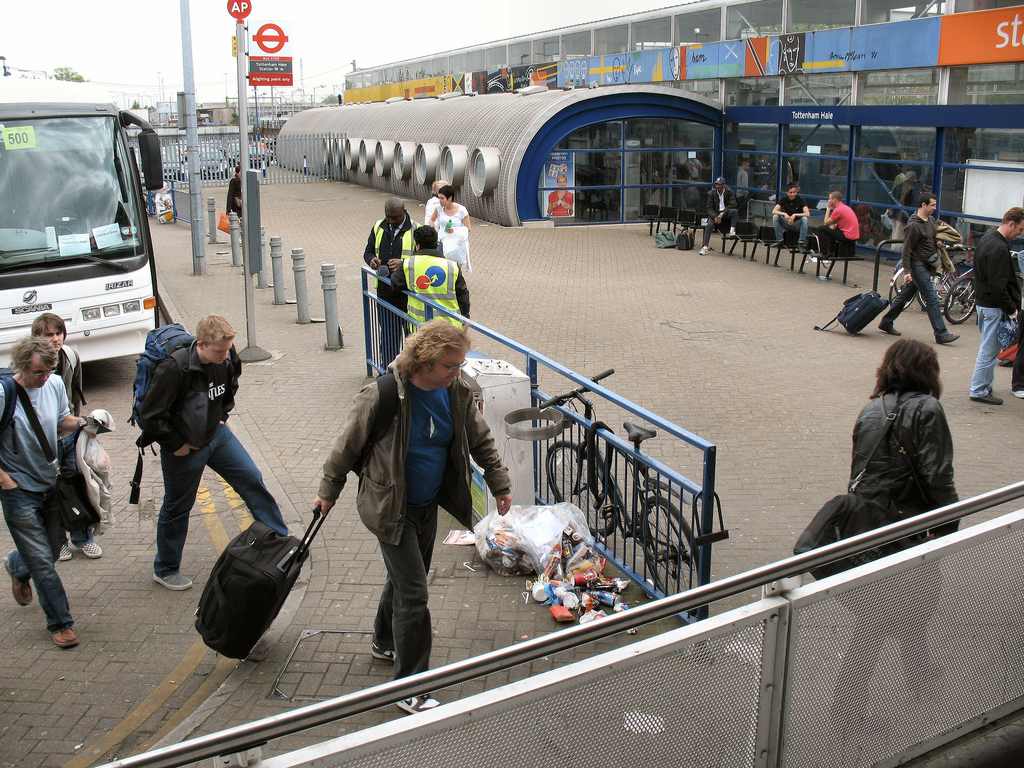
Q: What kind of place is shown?
A: It is a road.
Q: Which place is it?
A: It is a road.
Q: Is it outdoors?
A: Yes, it is outdoors.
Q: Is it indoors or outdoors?
A: It is outdoors.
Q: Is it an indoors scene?
A: No, it is outdoors.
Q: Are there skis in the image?
A: No, there are no skis.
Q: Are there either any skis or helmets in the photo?
A: No, there are no skis or helmets.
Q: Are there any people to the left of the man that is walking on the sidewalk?
A: Yes, there is a person to the left of the man.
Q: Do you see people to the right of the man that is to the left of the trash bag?
A: No, the person is to the left of the man.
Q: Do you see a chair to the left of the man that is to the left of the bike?
A: No, there is a person to the left of the man.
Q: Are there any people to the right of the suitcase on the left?
A: No, the person is to the left of the suitcase.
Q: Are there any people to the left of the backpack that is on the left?
A: Yes, there is a person to the left of the backpack.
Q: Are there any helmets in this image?
A: No, there are no helmets.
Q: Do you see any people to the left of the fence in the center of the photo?
A: Yes, there is a person to the left of the fence.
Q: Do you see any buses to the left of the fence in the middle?
A: No, there is a person to the left of the fence.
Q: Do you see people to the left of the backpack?
A: Yes, there is a person to the left of the backpack.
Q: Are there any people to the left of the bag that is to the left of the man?
A: Yes, there is a person to the left of the backpack.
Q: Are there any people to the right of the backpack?
A: No, the person is to the left of the backpack.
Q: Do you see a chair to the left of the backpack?
A: No, there is a person to the left of the backpack.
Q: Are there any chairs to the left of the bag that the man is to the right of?
A: No, there is a person to the left of the backpack.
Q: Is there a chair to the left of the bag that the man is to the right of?
A: No, there is a person to the left of the backpack.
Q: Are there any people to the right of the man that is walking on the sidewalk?
A: No, the person is to the left of the man.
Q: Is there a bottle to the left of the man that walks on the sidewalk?
A: No, there is a person to the left of the man.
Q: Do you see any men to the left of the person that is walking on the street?
A: Yes, there is a man to the left of the person.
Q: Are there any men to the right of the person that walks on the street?
A: No, the man is to the left of the person.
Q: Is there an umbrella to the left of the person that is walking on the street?
A: No, there is a man to the left of the person.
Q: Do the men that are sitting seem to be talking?
A: Yes, the men are talking.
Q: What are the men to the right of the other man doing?
A: The men are talking.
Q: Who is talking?
A: The men are talking.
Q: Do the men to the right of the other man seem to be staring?
A: No, the men are talking.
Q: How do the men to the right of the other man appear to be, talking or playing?
A: The men are talking.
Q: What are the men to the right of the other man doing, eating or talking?
A: The men are talking.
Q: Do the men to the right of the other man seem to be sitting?
A: Yes, the men are sitting.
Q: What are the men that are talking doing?
A: The men are sitting.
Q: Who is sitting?
A: The men are sitting.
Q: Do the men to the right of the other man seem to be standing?
A: No, the men are sitting.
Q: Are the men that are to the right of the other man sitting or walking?
A: The men are sitting.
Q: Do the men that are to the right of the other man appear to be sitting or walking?
A: The men are sitting.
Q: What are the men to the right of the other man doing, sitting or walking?
A: The men are sitting.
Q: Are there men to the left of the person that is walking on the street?
A: Yes, there are men to the left of the person.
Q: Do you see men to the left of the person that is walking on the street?
A: Yes, there are men to the left of the person.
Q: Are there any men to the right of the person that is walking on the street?
A: No, the men are to the left of the person.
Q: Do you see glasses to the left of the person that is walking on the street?
A: No, there are men to the left of the person.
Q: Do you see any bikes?
A: Yes, there is a bike.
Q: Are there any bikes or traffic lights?
A: Yes, there is a bike.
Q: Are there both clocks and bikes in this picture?
A: No, there is a bike but no clocks.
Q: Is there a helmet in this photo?
A: No, there are no helmets.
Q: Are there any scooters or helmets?
A: No, there are no helmets or scooters.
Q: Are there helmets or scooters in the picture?
A: No, there are no helmets or scooters.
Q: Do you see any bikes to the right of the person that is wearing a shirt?
A: Yes, there is a bike to the right of the person.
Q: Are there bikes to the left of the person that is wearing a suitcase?
A: No, the bike is to the right of the person.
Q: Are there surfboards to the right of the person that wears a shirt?
A: No, there is a bike to the right of the person.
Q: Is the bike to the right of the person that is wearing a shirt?
A: Yes, the bike is to the right of the person.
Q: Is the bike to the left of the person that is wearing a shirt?
A: No, the bike is to the right of the person.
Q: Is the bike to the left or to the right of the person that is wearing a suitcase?
A: The bike is to the right of the person.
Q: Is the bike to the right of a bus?
A: No, the bike is to the right of a suitcase.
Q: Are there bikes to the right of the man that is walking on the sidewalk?
A: Yes, there is a bike to the right of the man.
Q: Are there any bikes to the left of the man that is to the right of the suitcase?
A: No, the bike is to the right of the man.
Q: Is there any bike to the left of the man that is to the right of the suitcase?
A: No, the bike is to the right of the man.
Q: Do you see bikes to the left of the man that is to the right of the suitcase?
A: No, the bike is to the right of the man.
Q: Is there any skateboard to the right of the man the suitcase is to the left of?
A: No, there is a bike to the right of the man.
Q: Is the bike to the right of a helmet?
A: No, the bike is to the right of the man.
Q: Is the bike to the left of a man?
A: No, the bike is to the right of a man.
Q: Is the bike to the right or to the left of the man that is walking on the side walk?
A: The bike is to the right of the man.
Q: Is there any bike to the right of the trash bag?
A: Yes, there is a bike to the right of the trash bag.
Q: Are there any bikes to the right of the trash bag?
A: Yes, there is a bike to the right of the trash bag.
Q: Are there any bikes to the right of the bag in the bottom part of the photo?
A: Yes, there is a bike to the right of the trash bag.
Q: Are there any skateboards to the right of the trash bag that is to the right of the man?
A: No, there is a bike to the right of the trash bag.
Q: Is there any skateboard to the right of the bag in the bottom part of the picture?
A: No, there is a bike to the right of the trash bag.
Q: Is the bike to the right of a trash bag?
A: Yes, the bike is to the right of a trash bag.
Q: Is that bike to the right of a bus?
A: No, the bike is to the right of a trash bag.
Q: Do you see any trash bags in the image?
A: Yes, there is a trash bag.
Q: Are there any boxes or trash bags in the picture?
A: Yes, there is a trash bag.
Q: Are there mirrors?
A: No, there are no mirrors.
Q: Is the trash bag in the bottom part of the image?
A: Yes, the trash bag is in the bottom of the image.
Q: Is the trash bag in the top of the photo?
A: No, the trash bag is in the bottom of the image.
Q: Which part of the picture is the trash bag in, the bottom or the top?
A: The trash bag is in the bottom of the image.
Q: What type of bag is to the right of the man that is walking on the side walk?
A: The bag is a trash bag.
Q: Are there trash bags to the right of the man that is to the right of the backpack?
A: Yes, there is a trash bag to the right of the man.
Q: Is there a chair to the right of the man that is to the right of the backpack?
A: No, there is a trash bag to the right of the man.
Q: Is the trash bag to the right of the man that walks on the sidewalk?
A: Yes, the trash bag is to the right of the man.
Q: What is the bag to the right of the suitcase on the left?
A: The bag is a trash bag.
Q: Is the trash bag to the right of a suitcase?
A: Yes, the trash bag is to the right of a suitcase.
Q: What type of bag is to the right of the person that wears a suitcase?
A: The bag is a trash bag.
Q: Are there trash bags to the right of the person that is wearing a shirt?
A: Yes, there is a trash bag to the right of the person.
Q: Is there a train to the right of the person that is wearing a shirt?
A: No, there is a trash bag to the right of the person.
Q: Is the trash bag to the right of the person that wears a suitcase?
A: Yes, the trash bag is to the right of the person.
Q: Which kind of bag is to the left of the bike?
A: The bag is a trash bag.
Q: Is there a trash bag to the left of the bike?
A: Yes, there is a trash bag to the left of the bike.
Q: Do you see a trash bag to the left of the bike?
A: Yes, there is a trash bag to the left of the bike.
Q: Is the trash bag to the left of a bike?
A: Yes, the trash bag is to the left of a bike.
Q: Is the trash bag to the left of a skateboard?
A: No, the trash bag is to the left of a bike.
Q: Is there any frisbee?
A: No, there are no frisbees.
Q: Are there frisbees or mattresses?
A: No, there are no frisbees or mattresses.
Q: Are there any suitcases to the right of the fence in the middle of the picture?
A: Yes, there is a suitcase to the right of the fence.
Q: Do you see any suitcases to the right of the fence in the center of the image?
A: Yes, there is a suitcase to the right of the fence.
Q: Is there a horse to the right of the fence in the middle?
A: No, there is a suitcase to the right of the fence.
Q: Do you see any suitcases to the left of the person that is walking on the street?
A: Yes, there is a suitcase to the left of the person.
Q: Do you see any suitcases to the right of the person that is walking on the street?
A: No, the suitcase is to the left of the person.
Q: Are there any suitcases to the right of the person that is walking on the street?
A: No, the suitcase is to the left of the person.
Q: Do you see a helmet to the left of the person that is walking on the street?
A: No, there is a suitcase to the left of the person.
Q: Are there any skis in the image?
A: No, there are no skis.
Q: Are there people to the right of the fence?
A: Yes, there is a person to the right of the fence.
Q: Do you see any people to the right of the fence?
A: Yes, there is a person to the right of the fence.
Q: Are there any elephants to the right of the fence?
A: No, there is a person to the right of the fence.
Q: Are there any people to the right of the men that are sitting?
A: Yes, there is a person to the right of the men.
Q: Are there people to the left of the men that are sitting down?
A: No, the person is to the right of the men.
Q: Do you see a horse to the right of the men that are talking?
A: No, there is a person to the right of the men.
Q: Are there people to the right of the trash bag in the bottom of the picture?
A: Yes, there is a person to the right of the trash bag.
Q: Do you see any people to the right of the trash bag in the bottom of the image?
A: Yes, there is a person to the right of the trash bag.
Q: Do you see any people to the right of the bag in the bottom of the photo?
A: Yes, there is a person to the right of the trash bag.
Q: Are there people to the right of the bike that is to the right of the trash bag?
A: Yes, there is a person to the right of the bike.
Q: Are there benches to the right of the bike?
A: No, there is a person to the right of the bike.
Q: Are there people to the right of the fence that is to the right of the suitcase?
A: Yes, there is a person to the right of the fence.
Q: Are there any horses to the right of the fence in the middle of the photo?
A: No, there is a person to the right of the fence.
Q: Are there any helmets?
A: No, there are no helmets.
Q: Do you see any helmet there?
A: No, there are no helmets.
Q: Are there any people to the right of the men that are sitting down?
A: Yes, there is a person to the right of the men.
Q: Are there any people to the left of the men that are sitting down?
A: No, the person is to the right of the men.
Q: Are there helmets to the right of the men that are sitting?
A: No, there is a person to the right of the men.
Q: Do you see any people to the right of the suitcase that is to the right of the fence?
A: Yes, there is a person to the right of the suitcase.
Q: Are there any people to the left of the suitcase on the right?
A: No, the person is to the right of the suitcase.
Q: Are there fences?
A: Yes, there is a fence.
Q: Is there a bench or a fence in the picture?
A: Yes, there is a fence.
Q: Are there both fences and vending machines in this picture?
A: No, there is a fence but no vending machines.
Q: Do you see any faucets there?
A: No, there are no faucets.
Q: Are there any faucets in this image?
A: No, there are no faucets.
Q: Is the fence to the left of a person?
A: Yes, the fence is to the left of a person.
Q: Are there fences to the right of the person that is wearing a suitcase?
A: Yes, there is a fence to the right of the person.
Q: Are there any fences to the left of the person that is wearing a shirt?
A: No, the fence is to the right of the person.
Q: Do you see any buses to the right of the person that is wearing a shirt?
A: No, there is a fence to the right of the person.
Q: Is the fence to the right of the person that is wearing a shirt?
A: Yes, the fence is to the right of the person.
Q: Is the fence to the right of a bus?
A: No, the fence is to the right of the person.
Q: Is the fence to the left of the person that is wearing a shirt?
A: No, the fence is to the right of the person.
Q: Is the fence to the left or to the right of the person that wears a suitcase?
A: The fence is to the right of the person.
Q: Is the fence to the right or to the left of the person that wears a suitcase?
A: The fence is to the right of the person.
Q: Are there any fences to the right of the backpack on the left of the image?
A: Yes, there is a fence to the right of the backpack.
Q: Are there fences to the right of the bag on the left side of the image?
A: Yes, there is a fence to the right of the backpack.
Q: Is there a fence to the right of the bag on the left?
A: Yes, there is a fence to the right of the backpack.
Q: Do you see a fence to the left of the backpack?
A: No, the fence is to the right of the backpack.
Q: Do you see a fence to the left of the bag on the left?
A: No, the fence is to the right of the backpack.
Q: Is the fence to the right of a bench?
A: No, the fence is to the right of the backpack.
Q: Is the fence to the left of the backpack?
A: No, the fence is to the right of the backpack.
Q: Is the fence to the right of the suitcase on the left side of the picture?
A: Yes, the fence is to the right of the suitcase.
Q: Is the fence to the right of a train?
A: No, the fence is to the right of the suitcase.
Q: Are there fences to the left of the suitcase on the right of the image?
A: Yes, there is a fence to the left of the suitcase.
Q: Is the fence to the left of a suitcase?
A: Yes, the fence is to the left of a suitcase.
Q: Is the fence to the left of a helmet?
A: No, the fence is to the left of a suitcase.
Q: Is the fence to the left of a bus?
A: No, the fence is to the left of a person.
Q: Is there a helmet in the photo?
A: No, there are no helmets.